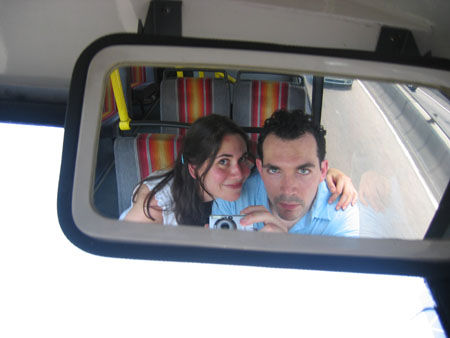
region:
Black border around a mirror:
[56, 30, 449, 278]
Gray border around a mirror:
[72, 44, 448, 258]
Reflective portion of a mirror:
[92, 59, 449, 242]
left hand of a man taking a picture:
[240, 206, 287, 234]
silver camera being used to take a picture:
[208, 212, 254, 229]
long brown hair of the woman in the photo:
[132, 113, 246, 224]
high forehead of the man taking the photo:
[261, 129, 323, 161]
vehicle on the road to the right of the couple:
[307, 75, 353, 90]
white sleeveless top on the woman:
[118, 168, 175, 225]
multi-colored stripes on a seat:
[175, 73, 218, 132]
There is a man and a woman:
[119, 109, 360, 255]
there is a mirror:
[53, 22, 449, 295]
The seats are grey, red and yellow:
[114, 71, 324, 238]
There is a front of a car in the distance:
[315, 76, 357, 94]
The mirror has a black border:
[45, 10, 448, 285]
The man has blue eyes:
[211, 108, 401, 249]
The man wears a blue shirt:
[206, 119, 377, 249]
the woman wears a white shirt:
[110, 118, 258, 237]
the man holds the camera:
[190, 98, 387, 240]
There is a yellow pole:
[111, 53, 135, 143]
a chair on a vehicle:
[159, 75, 226, 120]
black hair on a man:
[256, 103, 340, 140]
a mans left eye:
[297, 147, 325, 180]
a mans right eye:
[270, 153, 286, 175]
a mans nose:
[277, 174, 310, 197]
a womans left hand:
[322, 165, 367, 215]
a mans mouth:
[271, 193, 308, 218]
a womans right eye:
[213, 138, 228, 172]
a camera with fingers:
[206, 205, 260, 235]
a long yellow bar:
[107, 73, 127, 138]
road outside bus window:
[328, 88, 375, 147]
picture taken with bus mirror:
[56, 28, 449, 268]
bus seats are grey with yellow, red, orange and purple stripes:
[160, 77, 230, 109]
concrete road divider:
[399, 129, 447, 146]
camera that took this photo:
[208, 214, 254, 230]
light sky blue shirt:
[311, 210, 357, 231]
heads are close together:
[180, 107, 331, 220]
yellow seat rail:
[110, 66, 129, 130]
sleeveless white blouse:
[143, 174, 173, 220]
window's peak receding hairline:
[259, 128, 320, 142]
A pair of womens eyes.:
[203, 149, 249, 168]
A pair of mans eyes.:
[254, 157, 318, 185]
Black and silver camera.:
[201, 205, 256, 234]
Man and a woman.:
[170, 114, 324, 202]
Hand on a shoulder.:
[315, 153, 358, 215]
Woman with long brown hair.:
[138, 107, 247, 238]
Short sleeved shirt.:
[120, 166, 176, 221]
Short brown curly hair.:
[243, 107, 337, 155]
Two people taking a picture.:
[115, 119, 367, 239]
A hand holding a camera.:
[188, 203, 282, 237]